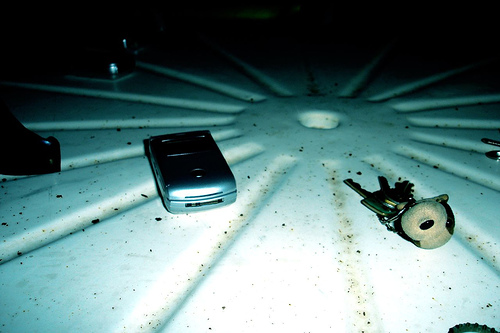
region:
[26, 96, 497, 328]
The brown specks on the white table.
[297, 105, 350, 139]
The hole in the middle of the table.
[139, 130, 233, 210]
The gray cellphone on the table.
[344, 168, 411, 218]
The keys on the table.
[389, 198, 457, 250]
The key chain the keys are attached to.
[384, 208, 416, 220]
The silver ring that is holding the keys to the key chain.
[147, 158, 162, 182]
The buttons on the side of the cellphone.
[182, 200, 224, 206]
The charger input on the cell phone.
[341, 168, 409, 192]
The points of the keys on the key chain.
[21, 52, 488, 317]
The indentions on the white table.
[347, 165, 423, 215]
The set of keys to the right of the phone.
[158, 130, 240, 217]
The gray cell phne.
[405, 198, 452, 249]
The round key chain on the set of keys.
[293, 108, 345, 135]
The whole in the middle of the white table.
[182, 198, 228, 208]
The opening to charge the phone.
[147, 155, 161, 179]
The buttons on the left side of the phone.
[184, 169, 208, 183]
The circle near the bottom of the lid of the phone.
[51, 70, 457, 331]
The brown specks on the white surface.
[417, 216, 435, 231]
The center hole of the key chain.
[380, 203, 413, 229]
The silver ring attaching the keys to the key chain.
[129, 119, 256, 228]
cell phone on the table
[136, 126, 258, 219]
flip style cell phone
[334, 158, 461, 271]
keys on the table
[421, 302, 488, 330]
edge of a bottle cap on the table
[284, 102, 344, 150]
hole in the center of the table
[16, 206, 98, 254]
groove in the table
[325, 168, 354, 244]
dirt on the table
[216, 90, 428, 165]
flat ring around the hole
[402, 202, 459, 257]
key chain on the keys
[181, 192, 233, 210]
charging port on the cell phone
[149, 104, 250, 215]
grey phone on table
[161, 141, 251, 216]
phone has metallic finish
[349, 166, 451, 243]
keychain is near phone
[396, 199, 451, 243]
white ring on keychain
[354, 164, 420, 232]
keys on ring are grey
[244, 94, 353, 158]
circular center of table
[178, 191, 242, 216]
dark charing jack on phone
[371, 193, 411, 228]
chrome and shiny key ring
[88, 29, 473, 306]
table under items is white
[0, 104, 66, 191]
black object left of phone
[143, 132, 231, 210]
A cell phone near the keys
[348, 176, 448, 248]
Keys by the cell phone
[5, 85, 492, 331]
Dirt on the surface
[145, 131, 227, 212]
The cell phone is closed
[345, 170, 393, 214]
A key on the ring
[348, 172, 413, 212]
Keys on the keychain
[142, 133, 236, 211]
The cell phone is silver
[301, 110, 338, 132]
A hole on the surface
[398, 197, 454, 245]
An item on the keychain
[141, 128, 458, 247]
A cellphone next to a keychain